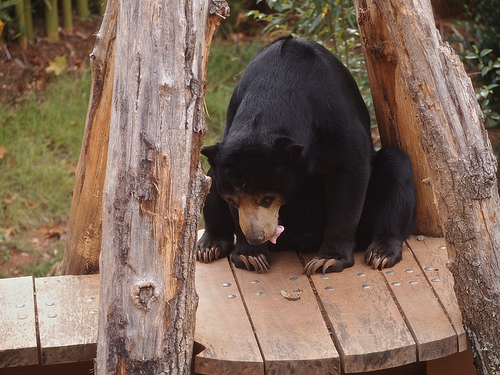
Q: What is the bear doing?
A: Eating.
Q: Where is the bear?
A: On a wooden bridge.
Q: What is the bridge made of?
A: Wood.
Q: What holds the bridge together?
A: Wood.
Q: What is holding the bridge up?
A: Tree trunks.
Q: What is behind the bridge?
A: Grass.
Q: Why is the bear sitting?
A: To eat.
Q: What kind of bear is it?
A: A black bear.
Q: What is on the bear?
A: Fur.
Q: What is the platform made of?
A: Wood.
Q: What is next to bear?
A: Tree.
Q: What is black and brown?
A: Bear.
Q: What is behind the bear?
A: Grass.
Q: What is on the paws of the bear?
A: Claws.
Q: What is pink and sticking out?
A: Tongue.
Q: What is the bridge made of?
A: Wood.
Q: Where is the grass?
A: Behind the bear.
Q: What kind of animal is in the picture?
A: Bear.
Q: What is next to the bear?
A: Wood log.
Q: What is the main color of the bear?
A: Black.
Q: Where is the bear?
A: On the wooden house.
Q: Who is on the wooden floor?
A: A bear.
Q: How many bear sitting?
A: One.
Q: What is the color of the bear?
A: Brown and black.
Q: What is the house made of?
A: Wood.